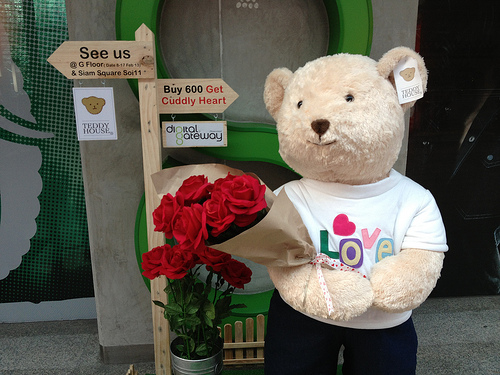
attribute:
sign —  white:
[162, 117, 234, 149]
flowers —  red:
[147, 175, 274, 283]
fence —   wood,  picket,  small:
[216, 309, 269, 374]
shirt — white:
[271, 163, 451, 333]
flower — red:
[133, 162, 333, 296]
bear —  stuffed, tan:
[256, 45, 447, 366]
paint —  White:
[0, 140, 44, 284]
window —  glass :
[1, 0, 93, 305]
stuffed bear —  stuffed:
[263, 46, 448, 373]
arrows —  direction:
[42, 36, 243, 121]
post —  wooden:
[126, 79, 174, 368]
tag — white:
[390, 58, 431, 107]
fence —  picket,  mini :
[210, 317, 266, 366]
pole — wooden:
[138, 78, 171, 373]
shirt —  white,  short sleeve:
[248, 186, 472, 341]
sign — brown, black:
[45, 33, 148, 81]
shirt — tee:
[264, 170, 449, 330]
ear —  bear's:
[376, 45, 427, 110]